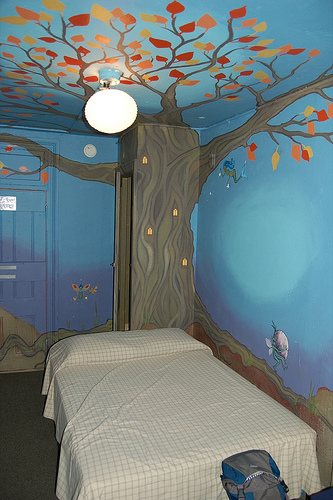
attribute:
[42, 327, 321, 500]
bed — tan, small, made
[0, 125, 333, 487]
wall — blue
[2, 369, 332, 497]
floor — gray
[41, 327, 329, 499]
bedspread — checkered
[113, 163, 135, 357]
closet door — opened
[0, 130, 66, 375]
room door — painted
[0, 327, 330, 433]
roots — painted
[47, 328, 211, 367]
pillow — covered